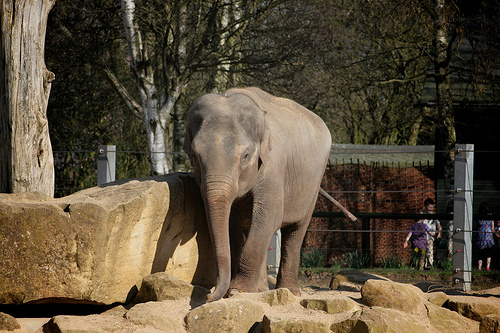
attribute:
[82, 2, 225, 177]
tree — white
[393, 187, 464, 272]
girl — little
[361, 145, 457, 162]
wire — gray, metal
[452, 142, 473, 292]
post — wood, metal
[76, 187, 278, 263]
rock wall — large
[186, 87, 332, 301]
elephant — standing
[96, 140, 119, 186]
post — gray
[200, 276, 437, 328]
stones — gray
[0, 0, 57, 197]
trunk — cracked, old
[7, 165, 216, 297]
rock — large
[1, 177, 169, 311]
rock — large, wall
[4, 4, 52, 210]
tree trunk — tall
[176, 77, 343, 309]
elephant — african, walking, young, baby, gray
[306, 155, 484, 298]
fence — black, metal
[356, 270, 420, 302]
rock — big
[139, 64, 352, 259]
elephant — gray